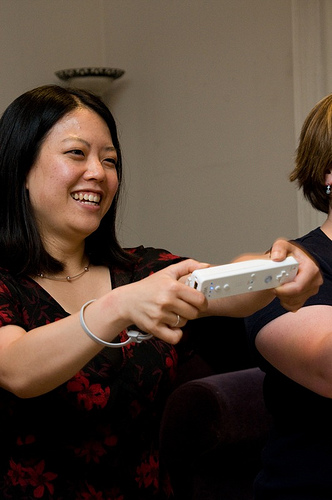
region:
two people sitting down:
[15, 75, 330, 290]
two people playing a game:
[16, 82, 326, 384]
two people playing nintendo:
[46, 97, 331, 303]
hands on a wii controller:
[89, 222, 310, 379]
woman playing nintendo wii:
[4, 99, 281, 435]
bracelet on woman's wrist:
[70, 283, 126, 359]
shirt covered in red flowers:
[22, 215, 167, 438]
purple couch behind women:
[48, 338, 274, 490]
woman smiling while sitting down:
[6, 42, 166, 216]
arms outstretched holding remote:
[2, 200, 312, 426]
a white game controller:
[154, 225, 308, 329]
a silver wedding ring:
[160, 307, 188, 342]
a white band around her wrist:
[69, 288, 140, 368]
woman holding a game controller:
[6, 88, 315, 462]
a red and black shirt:
[3, 227, 237, 495]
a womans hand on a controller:
[86, 260, 223, 367]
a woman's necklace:
[34, 251, 115, 300]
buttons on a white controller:
[205, 276, 234, 300]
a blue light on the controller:
[206, 276, 214, 303]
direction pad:
[270, 264, 302, 293]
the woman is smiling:
[2, 71, 128, 256]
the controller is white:
[171, 247, 309, 325]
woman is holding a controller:
[0, 62, 328, 398]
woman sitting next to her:
[205, 36, 328, 490]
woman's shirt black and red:
[2, 250, 216, 486]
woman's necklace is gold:
[20, 243, 120, 298]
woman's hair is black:
[2, 60, 128, 283]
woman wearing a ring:
[148, 296, 184, 332]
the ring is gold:
[157, 302, 192, 331]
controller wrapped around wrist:
[72, 281, 161, 369]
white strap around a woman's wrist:
[73, 293, 158, 356]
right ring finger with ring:
[158, 308, 189, 330]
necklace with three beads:
[10, 246, 122, 292]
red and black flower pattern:
[6, 405, 151, 492]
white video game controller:
[180, 248, 303, 306]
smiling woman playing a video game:
[1, 82, 301, 469]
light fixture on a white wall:
[45, 52, 136, 96]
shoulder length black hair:
[0, 81, 65, 280]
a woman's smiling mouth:
[62, 181, 111, 213]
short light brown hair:
[289, 87, 330, 184]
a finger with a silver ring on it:
[152, 307, 189, 339]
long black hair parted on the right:
[4, 87, 116, 152]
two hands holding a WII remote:
[171, 250, 321, 317]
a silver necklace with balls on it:
[18, 253, 101, 295]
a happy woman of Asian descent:
[1, 93, 132, 266]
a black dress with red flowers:
[5, 265, 173, 492]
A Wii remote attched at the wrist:
[64, 248, 308, 352]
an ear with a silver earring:
[305, 162, 330, 200]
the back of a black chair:
[154, 366, 263, 496]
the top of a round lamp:
[39, 51, 138, 104]